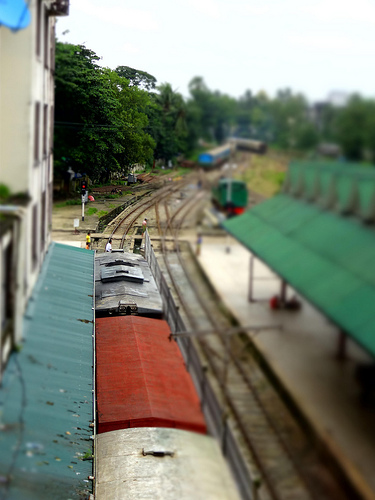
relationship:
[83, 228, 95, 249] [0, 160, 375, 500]
person on station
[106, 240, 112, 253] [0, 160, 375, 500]
people on station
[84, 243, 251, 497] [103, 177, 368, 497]
train on train tracks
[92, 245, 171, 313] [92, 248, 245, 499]
roof on train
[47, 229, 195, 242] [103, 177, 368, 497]
split on train tracks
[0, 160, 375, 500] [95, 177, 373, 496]
station on tracks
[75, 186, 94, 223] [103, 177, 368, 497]
people on train tracks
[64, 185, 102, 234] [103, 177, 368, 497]
people on train tracks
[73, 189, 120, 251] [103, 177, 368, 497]
people on train tracks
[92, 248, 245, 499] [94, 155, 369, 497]
train are on track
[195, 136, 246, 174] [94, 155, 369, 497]
trains on track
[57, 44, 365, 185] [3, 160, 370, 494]
forest surrounding station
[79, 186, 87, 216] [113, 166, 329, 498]
light near track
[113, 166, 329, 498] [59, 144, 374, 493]
track in yard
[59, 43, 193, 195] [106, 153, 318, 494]
trees by tracks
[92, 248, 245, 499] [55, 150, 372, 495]
train in station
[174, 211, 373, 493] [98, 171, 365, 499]
platform next to track